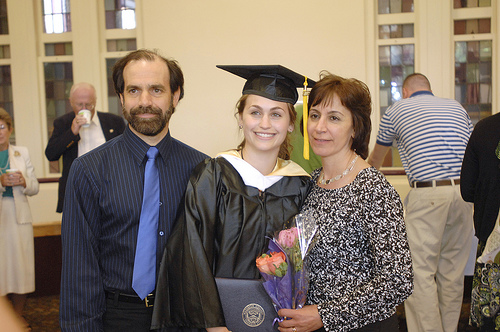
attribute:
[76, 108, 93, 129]
cup — white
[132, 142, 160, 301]
tie — blue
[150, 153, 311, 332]
graduation gown — black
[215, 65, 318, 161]
cap — black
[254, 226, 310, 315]
roses — pink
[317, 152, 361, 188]
necklace — silver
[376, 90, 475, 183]
shirt — White , blue, stripped , striped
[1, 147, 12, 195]
coat — green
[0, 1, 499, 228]
wall — white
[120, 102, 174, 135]
beard — black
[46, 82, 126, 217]
man — old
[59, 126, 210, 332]
shirt — BLUE , PINSTRIPED 